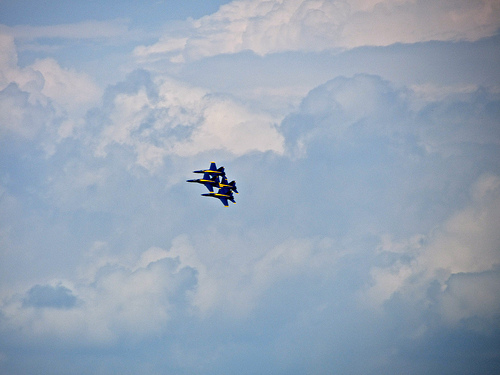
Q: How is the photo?
A: Clear.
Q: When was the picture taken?
A: During the day.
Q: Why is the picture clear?
A: Its daytime.